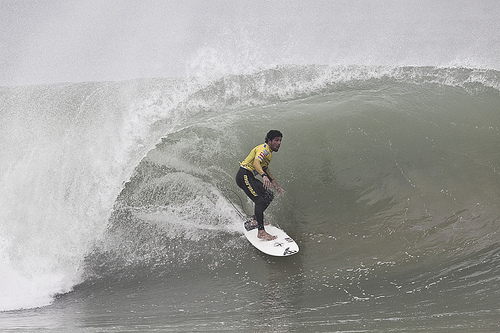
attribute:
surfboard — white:
[241, 215, 306, 261]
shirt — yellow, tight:
[240, 142, 270, 183]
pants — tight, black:
[236, 163, 276, 232]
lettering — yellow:
[243, 170, 262, 201]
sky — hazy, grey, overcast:
[7, 2, 499, 79]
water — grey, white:
[12, 61, 497, 331]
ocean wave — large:
[5, 61, 473, 300]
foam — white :
[4, 56, 230, 317]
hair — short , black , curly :
[268, 129, 281, 140]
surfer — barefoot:
[235, 129, 283, 239]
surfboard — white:
[238, 215, 298, 258]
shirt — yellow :
[241, 142, 270, 170]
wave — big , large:
[8, 66, 496, 311]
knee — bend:
[259, 189, 276, 199]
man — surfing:
[234, 132, 292, 240]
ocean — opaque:
[4, 76, 494, 326]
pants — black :
[231, 167, 271, 225]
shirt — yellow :
[236, 138, 276, 174]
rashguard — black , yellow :
[234, 141, 275, 222]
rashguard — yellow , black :
[235, 141, 279, 238]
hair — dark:
[265, 128, 283, 144]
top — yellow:
[242, 141, 272, 178]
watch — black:
[258, 170, 268, 179]